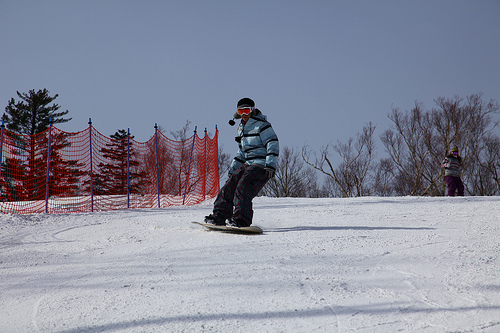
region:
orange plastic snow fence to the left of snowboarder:
[2, 115, 218, 215]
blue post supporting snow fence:
[86, 115, 92, 206]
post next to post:
[40, 116, 50, 208]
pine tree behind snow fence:
[2, 86, 82, 196]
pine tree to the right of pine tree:
[80, 125, 146, 192]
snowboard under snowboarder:
[192, 220, 260, 236]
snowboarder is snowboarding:
[187, 96, 282, 235]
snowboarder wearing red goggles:
[234, 105, 253, 114]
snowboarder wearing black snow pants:
[207, 163, 272, 225]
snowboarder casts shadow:
[263, 223, 437, 232]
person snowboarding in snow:
[185, 73, 285, 253]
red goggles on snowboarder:
[210, 95, 265, 124]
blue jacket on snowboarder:
[217, 112, 294, 180]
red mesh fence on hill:
[5, 119, 182, 224]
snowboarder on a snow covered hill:
[422, 135, 480, 220]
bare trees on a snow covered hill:
[305, 90, 434, 200]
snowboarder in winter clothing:
[188, 90, 289, 246]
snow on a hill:
[102, 243, 454, 320]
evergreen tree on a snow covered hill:
[5, 81, 87, 207]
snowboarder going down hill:
[186, 89, 311, 269]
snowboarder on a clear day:
[182, 78, 285, 251]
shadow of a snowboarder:
[274, 217, 436, 242]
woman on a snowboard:
[183, 83, 293, 268]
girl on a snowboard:
[172, 88, 302, 235]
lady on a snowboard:
[190, 73, 282, 331]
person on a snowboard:
[191, 75, 283, 255]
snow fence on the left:
[0, 114, 225, 226]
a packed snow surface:
[7, 201, 487, 331]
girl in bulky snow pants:
[199, 88, 283, 233]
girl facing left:
[178, 72, 293, 287]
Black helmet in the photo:
[238, 93, 255, 107]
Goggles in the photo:
[231, 109, 254, 116]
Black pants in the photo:
[207, 162, 272, 222]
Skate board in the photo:
[203, 218, 268, 237]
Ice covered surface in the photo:
[148, 239, 281, 286]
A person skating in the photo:
[200, 89, 281, 234]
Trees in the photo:
[377, 117, 436, 192]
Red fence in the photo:
[51, 137, 92, 208]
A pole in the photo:
[87, 119, 98, 211]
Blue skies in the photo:
[302, 30, 422, 108]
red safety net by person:
[94, 152, 135, 188]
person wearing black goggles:
[438, 138, 465, 185]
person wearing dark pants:
[223, 164, 251, 211]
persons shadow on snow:
[274, 210, 424, 235]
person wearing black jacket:
[244, 126, 279, 161]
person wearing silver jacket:
[238, 130, 257, 152]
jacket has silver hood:
[256, 106, 271, 123]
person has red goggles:
[236, 104, 258, 116]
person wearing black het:
[232, 92, 242, 107]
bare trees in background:
[391, 131, 449, 188]